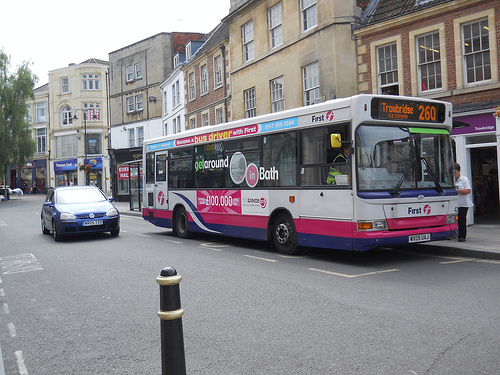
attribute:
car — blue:
[39, 184, 121, 241]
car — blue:
[37, 178, 137, 249]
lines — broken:
[0, 311, 47, 373]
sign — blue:
[52, 156, 101, 171]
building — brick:
[8, 44, 243, 258]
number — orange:
[417, 103, 437, 121]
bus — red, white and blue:
[134, 120, 497, 257]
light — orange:
[354, 219, 375, 232]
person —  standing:
[438, 159, 499, 233]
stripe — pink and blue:
[173, 194, 217, 229]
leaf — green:
[5, 151, 7, 158]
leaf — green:
[12, 152, 19, 160]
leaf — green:
[22, 145, 27, 152]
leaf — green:
[17, 132, 24, 137]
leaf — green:
[7, 92, 14, 109]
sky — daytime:
[1, 2, 226, 67]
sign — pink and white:
[196, 190, 241, 217]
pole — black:
[158, 269, 188, 371]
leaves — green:
[11, 80, 23, 107]